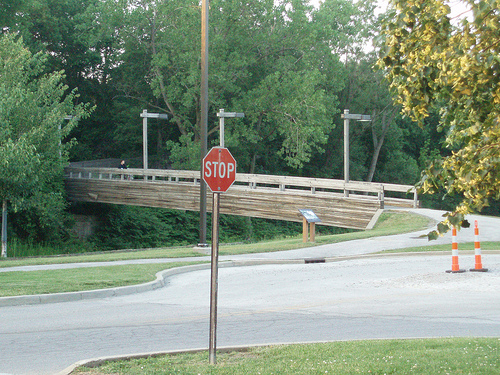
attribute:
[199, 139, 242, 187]
sign — stop, red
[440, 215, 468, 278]
cone — orange, thin, white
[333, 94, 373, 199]
lamp — street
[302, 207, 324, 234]
plaque — tourist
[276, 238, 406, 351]
street — concrete, grey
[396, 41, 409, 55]
leave — green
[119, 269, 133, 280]
grass — green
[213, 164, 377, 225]
bridge — wooden, light, pictured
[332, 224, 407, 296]
road — paved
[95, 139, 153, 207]
person — walking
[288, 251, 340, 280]
sewer — curb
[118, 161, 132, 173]
shrit — black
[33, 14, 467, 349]
picture — taken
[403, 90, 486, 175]
tree — leave